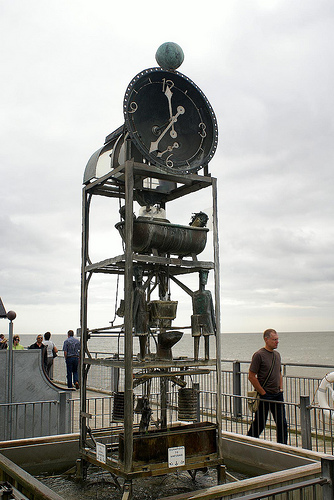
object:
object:
[155, 41, 185, 71]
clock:
[122, 66, 219, 174]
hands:
[261, 391, 270, 403]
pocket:
[259, 393, 284, 406]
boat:
[0, 347, 334, 498]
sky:
[229, 51, 309, 149]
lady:
[42, 331, 58, 376]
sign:
[166, 444, 186, 469]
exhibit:
[108, 41, 218, 491]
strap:
[258, 352, 276, 396]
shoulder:
[253, 346, 282, 361]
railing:
[232, 397, 334, 455]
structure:
[76, 124, 227, 500]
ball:
[155, 41, 185, 70]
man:
[246, 328, 288, 444]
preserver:
[318, 370, 334, 420]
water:
[220, 332, 254, 355]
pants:
[246, 391, 288, 445]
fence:
[215, 358, 261, 438]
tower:
[75, 41, 227, 499]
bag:
[247, 352, 276, 414]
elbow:
[247, 365, 255, 386]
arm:
[247, 352, 282, 392]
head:
[263, 328, 279, 349]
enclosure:
[6, 399, 107, 450]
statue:
[131, 267, 217, 363]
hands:
[149, 85, 186, 154]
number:
[128, 77, 207, 169]